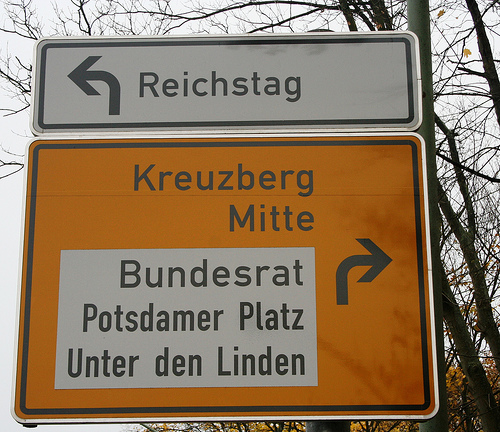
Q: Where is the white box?
A: On sign.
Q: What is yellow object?
A: Road Sign.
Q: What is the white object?
A: Road sign.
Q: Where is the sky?
A: Overhead.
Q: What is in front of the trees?
A: Street signs.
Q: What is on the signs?
A: Arrows and writing.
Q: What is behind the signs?
A: A tree.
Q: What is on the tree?
A: A few leaves.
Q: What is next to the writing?
A: Arrows.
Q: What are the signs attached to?
A: A pole.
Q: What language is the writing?
A: German.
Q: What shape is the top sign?
A: Rectangular.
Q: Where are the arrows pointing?
A: Left and Right.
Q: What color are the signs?
A: White and Yellow.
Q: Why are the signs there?
A: To provide directions.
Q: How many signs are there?
A: Two.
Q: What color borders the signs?
A: White.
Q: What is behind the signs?
A: Trees.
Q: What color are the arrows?
A: Black.